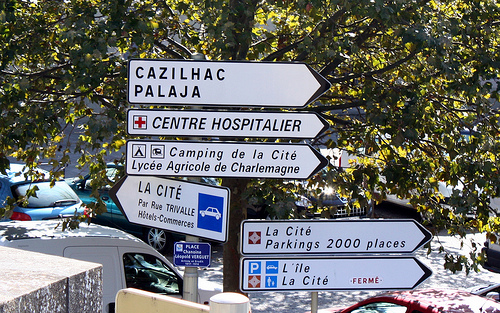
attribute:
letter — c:
[133, 64, 143, 79]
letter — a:
[145, 65, 154, 84]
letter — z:
[156, 65, 169, 77]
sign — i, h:
[125, 54, 325, 106]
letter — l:
[177, 65, 187, 81]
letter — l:
[156, 85, 164, 97]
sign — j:
[124, 50, 328, 109]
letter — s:
[230, 117, 240, 133]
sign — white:
[131, 111, 352, 163]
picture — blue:
[196, 196, 237, 241]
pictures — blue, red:
[235, 257, 283, 292]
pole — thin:
[287, 279, 325, 311]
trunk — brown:
[224, 231, 253, 291]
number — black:
[323, 234, 373, 256]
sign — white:
[108, 0, 330, 100]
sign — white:
[131, 102, 349, 167]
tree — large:
[162, 0, 464, 197]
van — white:
[6, 211, 197, 290]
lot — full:
[47, 133, 459, 290]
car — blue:
[6, 160, 117, 209]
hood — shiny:
[316, 182, 347, 207]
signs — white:
[85, 36, 438, 290]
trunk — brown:
[213, 62, 263, 287]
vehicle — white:
[43, 192, 205, 291]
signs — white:
[136, 16, 241, 234]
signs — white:
[109, 67, 301, 271]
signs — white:
[91, 24, 319, 219]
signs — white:
[116, 56, 337, 187]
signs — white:
[80, 64, 333, 226]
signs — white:
[93, 25, 285, 190]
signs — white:
[195, 118, 372, 165]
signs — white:
[109, 50, 349, 235]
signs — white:
[115, 42, 322, 222]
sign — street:
[126, 56, 334, 109]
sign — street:
[124, 104, 332, 141]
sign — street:
[124, 138, 330, 182]